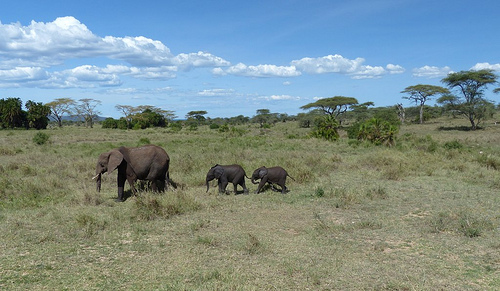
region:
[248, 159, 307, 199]
a baby elephant following other elephant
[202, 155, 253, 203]
a baby elephant following big elephant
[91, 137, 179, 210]
big elephant is walking on grass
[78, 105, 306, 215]
Three elephants walking on grass in field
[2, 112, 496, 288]
a green grassy field with elephants on it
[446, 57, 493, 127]
a green evergreen tree in field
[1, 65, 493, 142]
many green trees on field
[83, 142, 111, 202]
Big elephant has a white tusk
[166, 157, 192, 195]
a tail of the large elephant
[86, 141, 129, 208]
a side profile of elephant's ear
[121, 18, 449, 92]
The sky is blue and cloudy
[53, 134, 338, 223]
The elephants are walking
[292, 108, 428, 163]
The bushes are green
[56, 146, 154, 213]
The elephant has tusks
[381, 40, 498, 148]
The trees are tall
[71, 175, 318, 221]
The animals are on the ground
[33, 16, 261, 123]
The clouds are white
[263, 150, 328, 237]
The elephant has a tail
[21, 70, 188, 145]
The bushes in the back are short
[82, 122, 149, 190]
The elephant has large ears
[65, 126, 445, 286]
elephants on the field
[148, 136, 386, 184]
the field is open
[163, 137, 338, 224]
two elephants are small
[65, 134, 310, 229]
the elephants are gray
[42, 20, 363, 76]
the sky is clear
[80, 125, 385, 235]
the elephants are walking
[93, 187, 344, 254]
grass on the ground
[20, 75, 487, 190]
the field has trees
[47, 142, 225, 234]
the elephant has trunk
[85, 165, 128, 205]
the elephant's ears are wide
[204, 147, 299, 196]
two baby elephants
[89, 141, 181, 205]
a mother elephant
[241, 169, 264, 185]
a baby elephant holding onto a tail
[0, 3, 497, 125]
a beautiful blue sky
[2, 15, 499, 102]
white clouds in a sky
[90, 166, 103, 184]
a white tusk on an elephant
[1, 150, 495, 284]
dry savannah grass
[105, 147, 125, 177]
a large elephant ear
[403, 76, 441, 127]
a small green tree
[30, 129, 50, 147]
a small green shrub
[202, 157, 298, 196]
The two baby elephants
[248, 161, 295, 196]
The baby elephant on the right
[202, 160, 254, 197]
The baby elephant on the left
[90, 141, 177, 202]
The adult elephant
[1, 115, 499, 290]
The grass field the animals are in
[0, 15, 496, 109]
The clouds in the sky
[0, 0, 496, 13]
The blue sky above all the clouds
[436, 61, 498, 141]
The tallest tree shown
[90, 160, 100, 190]
The adult elephants trunk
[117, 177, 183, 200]
The shadow of the adult elephant